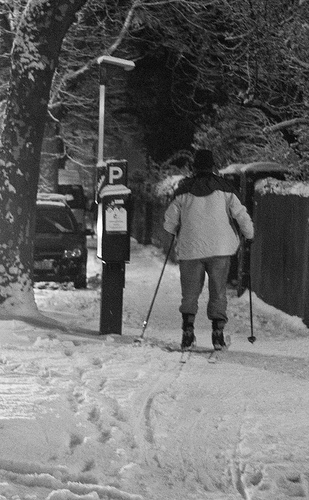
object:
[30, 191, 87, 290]
car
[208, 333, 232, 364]
board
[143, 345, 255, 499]
ski marks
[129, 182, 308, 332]
fence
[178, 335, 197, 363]
skis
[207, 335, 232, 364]
skis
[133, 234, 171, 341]
ski pole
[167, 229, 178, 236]
hand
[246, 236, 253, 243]
hand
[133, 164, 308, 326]
wall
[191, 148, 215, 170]
hat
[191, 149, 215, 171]
head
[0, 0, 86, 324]
tree trnk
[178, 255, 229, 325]
pants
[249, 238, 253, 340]
pole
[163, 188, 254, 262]
winter coat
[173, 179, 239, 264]
back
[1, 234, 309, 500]
ground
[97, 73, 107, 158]
pole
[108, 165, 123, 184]
letter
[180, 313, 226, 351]
boots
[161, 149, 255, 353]
man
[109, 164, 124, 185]
p.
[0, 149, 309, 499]
camera.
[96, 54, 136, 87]
light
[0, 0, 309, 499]
snow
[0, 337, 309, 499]
marks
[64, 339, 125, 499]
footprints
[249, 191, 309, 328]
board